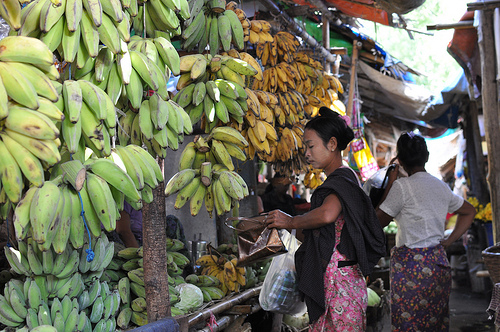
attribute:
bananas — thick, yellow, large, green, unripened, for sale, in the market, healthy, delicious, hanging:
[92, 164, 144, 208]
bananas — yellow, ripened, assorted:
[250, 119, 269, 144]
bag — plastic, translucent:
[259, 228, 309, 314]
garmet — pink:
[307, 217, 369, 330]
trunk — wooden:
[140, 160, 176, 326]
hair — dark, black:
[303, 105, 355, 150]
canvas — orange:
[292, 0, 393, 36]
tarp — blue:
[350, 30, 416, 84]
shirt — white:
[379, 173, 467, 249]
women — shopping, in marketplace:
[259, 102, 370, 329]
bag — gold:
[225, 213, 290, 264]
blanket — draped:
[285, 166, 386, 323]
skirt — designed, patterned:
[390, 245, 452, 330]